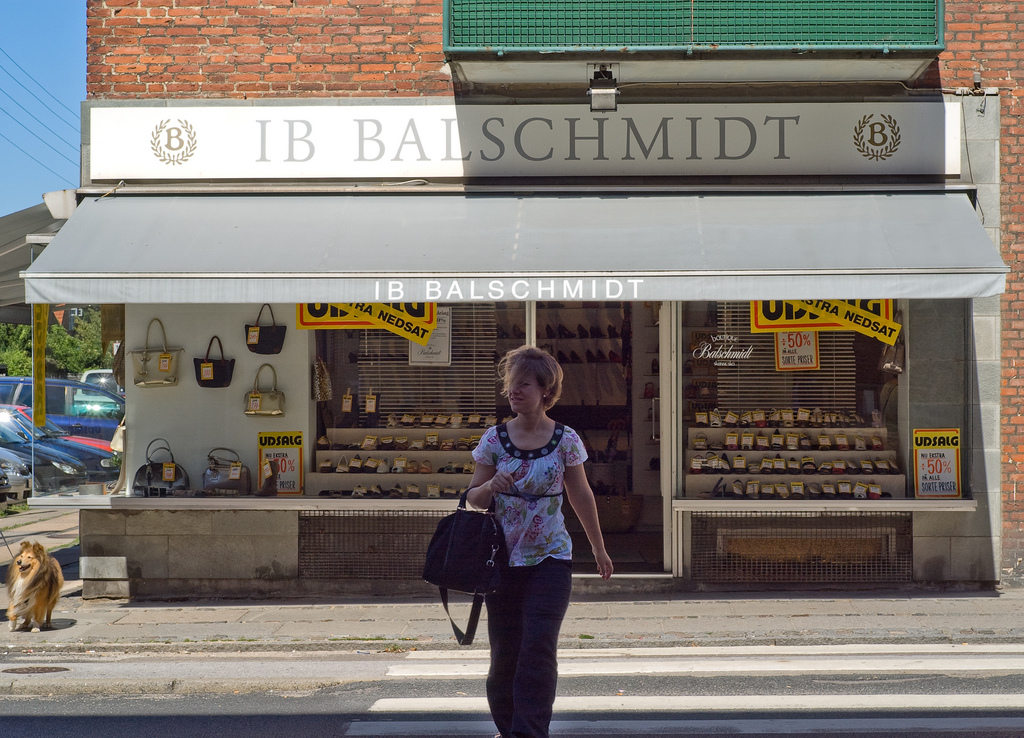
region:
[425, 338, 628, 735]
woman crossing the road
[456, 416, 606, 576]
woman wearing a blouse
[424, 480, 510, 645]
woman holding a hand bag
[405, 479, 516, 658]
woman's handbag is large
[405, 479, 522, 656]
woman's handbag is black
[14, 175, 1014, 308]
awning over store is gray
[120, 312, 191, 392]
silver purse hanging on wall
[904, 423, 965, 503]
sign displayed in window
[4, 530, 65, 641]
dog standing on sidewalk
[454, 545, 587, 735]
Woman wearing pants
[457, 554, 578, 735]
Woman is wearing pants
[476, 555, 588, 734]
Woman wearing dark colored pants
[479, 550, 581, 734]
Woman is wearing dark colored pants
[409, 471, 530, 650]
Woman carrying a bag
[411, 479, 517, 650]
Woman carrying a black bag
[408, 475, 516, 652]
Woman is carrying a black bag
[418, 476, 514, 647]
Woman carrying a black purse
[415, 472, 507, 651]
Woman is carrying a black purse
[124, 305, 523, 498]
bags and shoes displayed behind a window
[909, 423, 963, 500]
a yellow sign with black writing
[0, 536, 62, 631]
a yellow dog with long hair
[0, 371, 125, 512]
a row of parked cars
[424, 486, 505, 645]
a black purse with a silver zipper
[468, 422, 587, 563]
a white blouse with a black neck border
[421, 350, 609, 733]
blonde woman carrying a black purse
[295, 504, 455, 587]
a brown grilled air vent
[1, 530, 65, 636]
a dog walking with a leash around its neck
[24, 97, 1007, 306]
a banner over a silver canopy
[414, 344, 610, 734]
a woman crossing the street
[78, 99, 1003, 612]
a shoe store named IB Balschmidt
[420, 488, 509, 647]
a handbag on a woman's arm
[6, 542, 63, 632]
a hairy dog on the sidewalk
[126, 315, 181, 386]
a golden handbag hanging on a wall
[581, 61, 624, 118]
a light suspended from the ceiling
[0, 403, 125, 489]
a black car parked in a parking lot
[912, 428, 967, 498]
a sale sign in a shop window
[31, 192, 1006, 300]
a gray awning over a shop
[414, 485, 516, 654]
the purse is black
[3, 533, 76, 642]
the dog is brown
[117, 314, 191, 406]
the bag is silver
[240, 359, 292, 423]
the bag is silver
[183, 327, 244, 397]
the bag is black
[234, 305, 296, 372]
the bag is black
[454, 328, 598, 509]
the woman is blonde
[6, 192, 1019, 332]
the awning is outside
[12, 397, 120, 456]
the car is red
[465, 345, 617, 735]
lady is walking across the street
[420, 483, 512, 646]
bag is on the ladies arm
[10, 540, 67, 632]
dog is standing beside the road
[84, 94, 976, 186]
sign is above the awning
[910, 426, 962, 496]
sign is in the window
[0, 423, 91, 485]
car is parked outside of building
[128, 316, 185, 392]
bag is hanging on display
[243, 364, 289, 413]
bag is hanging on display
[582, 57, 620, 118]
light is hanging above the awning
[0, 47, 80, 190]
power cables are in the sky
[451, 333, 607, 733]
a women walking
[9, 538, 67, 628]
a dog on the sidewalk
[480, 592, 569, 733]
women is wearing pants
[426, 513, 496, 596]
a black bag